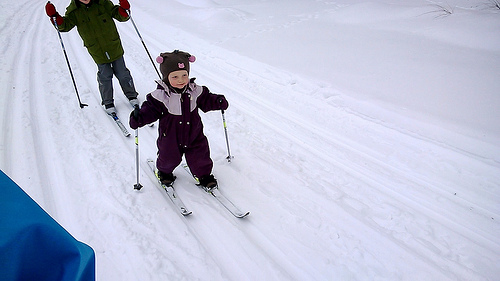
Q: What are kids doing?
A: Skiing.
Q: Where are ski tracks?
A: On the snow.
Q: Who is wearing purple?
A: Little girl.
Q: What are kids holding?
A: Ski poles.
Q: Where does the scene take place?
A: On a ski slope.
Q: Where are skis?
A: Under the kids' feet.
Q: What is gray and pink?
A: Little girl's hat.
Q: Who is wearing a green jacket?
A: Kid in the back.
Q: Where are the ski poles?
A: In the kids' hands.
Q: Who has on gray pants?
A: Kid in back.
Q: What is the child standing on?
A: Skis.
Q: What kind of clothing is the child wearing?
A: Ski Suit.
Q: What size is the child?
A: Small.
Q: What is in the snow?
A: Ski tracks.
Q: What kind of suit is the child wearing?
A: Snow.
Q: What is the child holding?
A: Ski poles.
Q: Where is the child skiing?
A: On a hill.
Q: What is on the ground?
A: Snow.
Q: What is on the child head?
A: Hat.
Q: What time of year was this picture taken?
A: Winter.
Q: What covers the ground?
A: Snow.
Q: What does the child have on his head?
A: A hat.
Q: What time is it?
A: Morning.